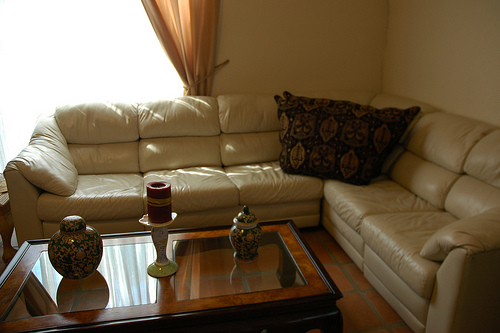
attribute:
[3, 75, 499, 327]
sectional — white, leather, is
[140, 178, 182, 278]
candle — red, small, large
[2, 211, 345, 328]
table — brown, wooden, glass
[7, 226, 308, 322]
top — glass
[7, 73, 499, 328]
sofa — sectional, beige, leather, white, bisectional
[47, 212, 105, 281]
vase — black, gold, small, round, ginger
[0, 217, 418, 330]
flooring — brown, tiles, stone, tile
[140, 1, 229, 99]
curtain — pulled back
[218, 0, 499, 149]
wall — beige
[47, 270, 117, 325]
reflection — vase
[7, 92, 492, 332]
couch — leather, cream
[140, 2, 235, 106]
curtains — gold, hanging, tied back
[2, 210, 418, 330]
floors — tiled, brown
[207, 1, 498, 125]
walls — cream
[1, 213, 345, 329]
coffee table — glass topped, wooden framed, wood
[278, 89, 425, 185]
pillow — couch's, large, fluffy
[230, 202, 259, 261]
pot — small, floral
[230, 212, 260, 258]
design — floral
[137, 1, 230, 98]
window dressing — long, tan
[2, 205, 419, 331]
stone — red